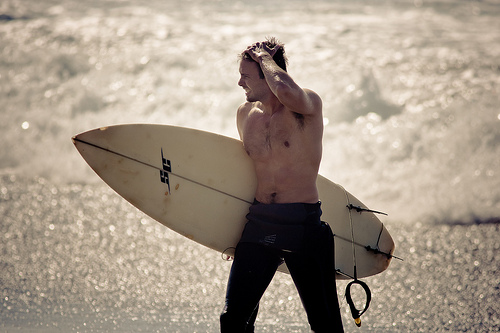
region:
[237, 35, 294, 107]
Brown hair on man's head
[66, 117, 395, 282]
A white surfboard being carried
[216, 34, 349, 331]
Man wearing a black wetsuit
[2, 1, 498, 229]
The ocean in the background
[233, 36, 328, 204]
The man is shirtless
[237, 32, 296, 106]
Man's hand on his head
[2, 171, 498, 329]
Sand is on the beach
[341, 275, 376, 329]
Black rope attached to surfboard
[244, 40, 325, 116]
Arm of a surfer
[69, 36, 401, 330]
Man is holding a surfboard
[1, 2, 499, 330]
A surfer on the beach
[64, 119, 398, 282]
A dirty white surfboard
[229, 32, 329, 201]
Surfer wearing no shirt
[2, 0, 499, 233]
The ocean behind the surfer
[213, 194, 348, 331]
A black colored wetsuit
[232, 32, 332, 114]
Man with hand on his head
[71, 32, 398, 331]
A surfer carrying a surfboard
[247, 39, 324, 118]
Arm of a man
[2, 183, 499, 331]
Sand on the beach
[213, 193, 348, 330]
The wetsuit of the surfer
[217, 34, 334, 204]
The bare portion of the surfer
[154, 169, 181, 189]
The 's' printed on the bottom of the board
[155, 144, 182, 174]
The 'c' printed on the bottom of the board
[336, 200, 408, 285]
The fins on the bottom of the board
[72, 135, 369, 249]
The line down the middle of the board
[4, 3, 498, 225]
The waves behind the man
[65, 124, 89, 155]
The point of the surfboard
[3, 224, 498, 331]
The shallow water behind the surfer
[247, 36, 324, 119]
The man's left arm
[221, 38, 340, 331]
a man walking out of the ocean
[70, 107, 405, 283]
the surfboard the man is holding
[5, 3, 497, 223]
the ocean behind the man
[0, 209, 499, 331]
the beach next to the woman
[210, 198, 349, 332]
the wetsuit the man is wearing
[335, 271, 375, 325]
the strap attached to the board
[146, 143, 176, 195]
the logo on the surfboard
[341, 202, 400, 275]
the fins on the board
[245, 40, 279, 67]
the man's hand on his head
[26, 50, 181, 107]
some of the water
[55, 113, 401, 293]
the surfboard is white in color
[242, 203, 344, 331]
the pants are black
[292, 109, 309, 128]
hiar is under the armpit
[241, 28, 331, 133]
hand is touching the head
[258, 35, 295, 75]
the hair is black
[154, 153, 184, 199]
sc is written on the board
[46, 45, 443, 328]
the guy is on the beach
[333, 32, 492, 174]
water is in the background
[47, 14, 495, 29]
ocean is in the background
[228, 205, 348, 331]
the swimsuit is wet